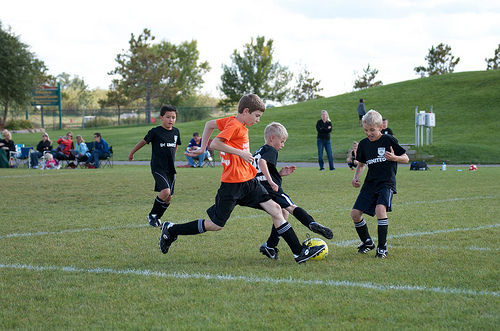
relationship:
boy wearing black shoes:
[349, 109, 409, 258] [358, 235, 391, 262]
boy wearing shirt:
[126, 100, 185, 229] [140, 122, 181, 160]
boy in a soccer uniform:
[349, 109, 409, 258] [352, 134, 405, 215]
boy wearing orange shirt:
[158, 93, 332, 264] [216, 115, 258, 183]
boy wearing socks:
[349, 109, 409, 258] [351, 217, 389, 247]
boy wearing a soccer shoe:
[349, 109, 409, 258] [375, 245, 388, 259]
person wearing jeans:
[306, 103, 342, 166] [311, 145, 336, 170]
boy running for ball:
[151, 89, 333, 274] [274, 204, 344, 276]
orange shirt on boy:
[184, 93, 256, 199] [184, 91, 337, 296]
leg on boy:
[372, 188, 389, 245] [349, 109, 409, 258]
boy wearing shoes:
[244, 109, 336, 265] [142, 199, 192, 258]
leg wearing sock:
[260, 217, 342, 277] [167, 202, 207, 242]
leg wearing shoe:
[260, 217, 342, 277] [140, 204, 185, 268]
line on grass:
[45, 240, 484, 316] [386, 222, 486, 310]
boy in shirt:
[355, 121, 445, 237] [200, 106, 260, 187]